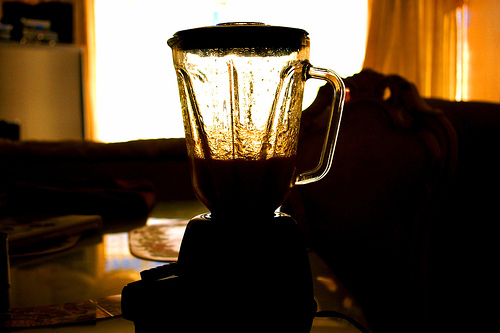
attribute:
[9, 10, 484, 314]
photo — dimly lit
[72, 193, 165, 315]
counter top — white, shiny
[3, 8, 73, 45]
books — stacked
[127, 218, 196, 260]
stuff — stacked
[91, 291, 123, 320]
stuff — stacked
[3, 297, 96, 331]
stuff — stacked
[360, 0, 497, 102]
white curtains — open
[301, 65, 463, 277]
man — sitting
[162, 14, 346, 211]
pitcher — glass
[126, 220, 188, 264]
placemat — decorated, green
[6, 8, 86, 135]
walls — white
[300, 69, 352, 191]
handle — glass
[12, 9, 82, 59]
shelf — wooden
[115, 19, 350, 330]
blender — glass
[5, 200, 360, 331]
table — reflective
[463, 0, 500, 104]
curtain — open, off white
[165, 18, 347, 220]
blender — clear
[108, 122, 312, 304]
placemat — white, plastic, green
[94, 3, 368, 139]
window — sunlit, blurry, glass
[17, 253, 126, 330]
counter — white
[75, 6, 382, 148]
glass — transparent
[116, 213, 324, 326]
stand — black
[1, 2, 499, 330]
sunlight — golden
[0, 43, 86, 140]
shelf — white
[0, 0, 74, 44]
cds — stacked